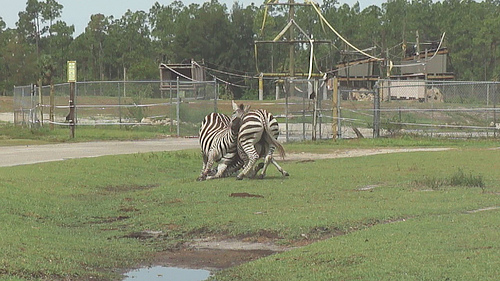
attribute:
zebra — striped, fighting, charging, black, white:
[195, 99, 251, 181]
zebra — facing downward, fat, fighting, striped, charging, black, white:
[226, 104, 290, 179]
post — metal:
[68, 82, 77, 138]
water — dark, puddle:
[121, 259, 214, 279]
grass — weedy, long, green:
[1, 130, 499, 278]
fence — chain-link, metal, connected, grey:
[12, 79, 499, 146]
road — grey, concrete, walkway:
[0, 129, 331, 168]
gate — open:
[175, 75, 220, 138]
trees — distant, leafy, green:
[0, 0, 500, 96]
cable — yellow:
[309, 1, 384, 64]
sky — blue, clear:
[0, 0, 499, 35]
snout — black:
[229, 117, 243, 140]